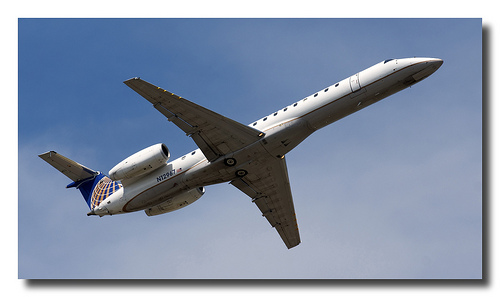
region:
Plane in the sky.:
[27, 39, 450, 256]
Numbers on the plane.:
[145, 166, 191, 186]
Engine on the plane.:
[101, 139, 183, 184]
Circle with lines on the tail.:
[51, 165, 122, 209]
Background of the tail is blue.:
[71, 175, 153, 220]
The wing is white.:
[135, 78, 252, 147]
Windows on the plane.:
[249, 78, 348, 126]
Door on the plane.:
[337, 65, 367, 98]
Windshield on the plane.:
[374, 48, 409, 72]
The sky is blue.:
[33, 36, 118, 111]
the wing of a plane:
[126, 66, 266, 166]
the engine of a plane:
[105, 137, 174, 187]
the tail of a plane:
[33, 143, 136, 215]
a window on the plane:
[333, 78, 345, 89]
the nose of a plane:
[420, 50, 452, 75]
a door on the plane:
[346, 68, 363, 95]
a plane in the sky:
[33, 43, 449, 253]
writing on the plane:
[153, 167, 175, 182]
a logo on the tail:
[83, 171, 124, 211]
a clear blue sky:
[19, 18, 484, 281]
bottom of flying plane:
[160, 46, 443, 223]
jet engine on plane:
[103, 142, 176, 189]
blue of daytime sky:
[265, 28, 341, 67]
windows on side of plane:
[254, 77, 345, 127]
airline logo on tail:
[85, 172, 124, 207]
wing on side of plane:
[124, 72, 244, 149]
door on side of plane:
[342, 75, 364, 98]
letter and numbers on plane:
[150, 163, 180, 185]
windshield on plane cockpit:
[378, 52, 399, 72]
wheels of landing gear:
[215, 149, 250, 183]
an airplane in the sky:
[69, 22, 453, 291]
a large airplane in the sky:
[83, 48, 475, 290]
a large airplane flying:
[43, 42, 483, 295]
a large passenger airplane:
[64, 42, 486, 187]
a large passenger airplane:
[89, 59, 472, 293]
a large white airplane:
[14, 77, 478, 200]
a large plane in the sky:
[68, 67, 497, 285]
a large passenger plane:
[77, 54, 497, 286]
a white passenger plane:
[73, 57, 478, 221]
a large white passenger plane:
[57, 67, 484, 274]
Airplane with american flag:
[143, 164, 192, 191]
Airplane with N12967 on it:
[145, 164, 180, 184]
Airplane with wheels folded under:
[216, 150, 261, 182]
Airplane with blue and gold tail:
[42, 139, 136, 221]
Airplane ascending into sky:
[37, 42, 462, 222]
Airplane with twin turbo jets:
[101, 139, 211, 221]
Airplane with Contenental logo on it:
[40, 135, 217, 236]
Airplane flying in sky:
[48, 45, 448, 214]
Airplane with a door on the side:
[347, 67, 366, 97]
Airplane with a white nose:
[367, 50, 451, 93]